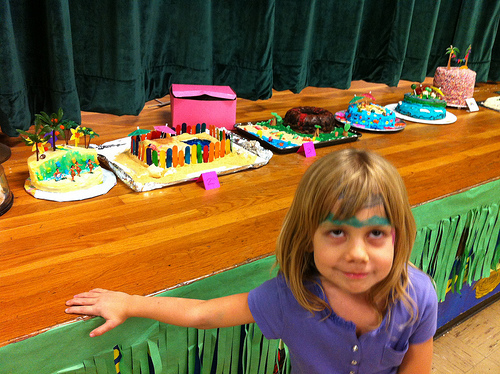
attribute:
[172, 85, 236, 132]
box — in the picture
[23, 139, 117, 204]
cake — in the picture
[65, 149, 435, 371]
little girl — in the picture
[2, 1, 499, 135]
green curtain — in the picture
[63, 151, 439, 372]
girl — in the picture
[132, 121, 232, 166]
fence — small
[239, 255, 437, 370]
shirt — purple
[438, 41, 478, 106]
cakes — colorful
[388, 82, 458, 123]
cakes — colorful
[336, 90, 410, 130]
cakes — colorful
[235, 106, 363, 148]
cakes — colorful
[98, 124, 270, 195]
cakes — colorful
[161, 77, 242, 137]
box — in the picture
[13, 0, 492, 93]
curtain — in the picture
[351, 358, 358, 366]
button — small, white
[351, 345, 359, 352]
button — small, white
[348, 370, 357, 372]
button — small, white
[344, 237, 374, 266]
nose — in the picture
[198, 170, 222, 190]
note — small, pink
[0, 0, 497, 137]
curtain — blue, velvet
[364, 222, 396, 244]
left eye — in the picture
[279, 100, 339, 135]
cake — in the picture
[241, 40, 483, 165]
cakes — in the picture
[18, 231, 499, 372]
paper — in the picture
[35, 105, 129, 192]
cake — in the picture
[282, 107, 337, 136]
cake — in the picture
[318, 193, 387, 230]
paint — in the picture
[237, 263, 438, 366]
shirt — purple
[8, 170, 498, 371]
fringe — green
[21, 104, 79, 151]
trees — plastic